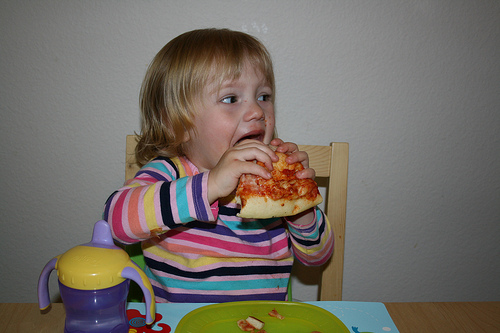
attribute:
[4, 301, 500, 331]
table — tan, wood, wooden, brown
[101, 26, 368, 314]
child — eating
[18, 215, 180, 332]
cup — lavendar, plastic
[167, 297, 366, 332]
plate — green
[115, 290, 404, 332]
place mat — blue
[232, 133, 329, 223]
pizza — plain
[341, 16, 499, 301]
wall — grey, white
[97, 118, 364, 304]
chair — tan, wooden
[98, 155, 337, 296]
shirt — striped